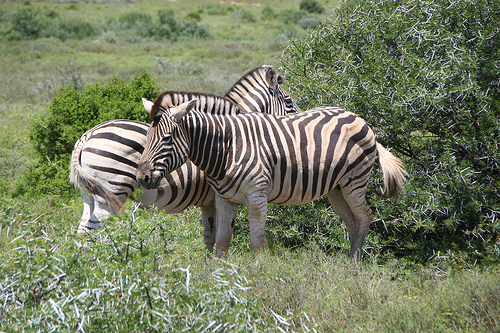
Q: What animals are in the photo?
A: Zebras.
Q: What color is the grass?
A: Green.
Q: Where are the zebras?
A: In a field.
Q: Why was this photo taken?
A: To show zebras.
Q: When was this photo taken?
A: In the daytime.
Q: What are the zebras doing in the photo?
A: Standing.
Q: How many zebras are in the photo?
A: Two.